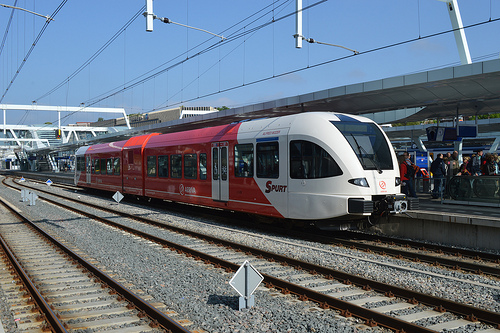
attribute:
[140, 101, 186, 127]
cocrete — off-white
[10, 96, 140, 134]
metal — railing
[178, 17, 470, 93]
wires — metal, cable wires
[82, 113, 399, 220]
train — red and white, engine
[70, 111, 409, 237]
train — set 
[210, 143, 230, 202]
doors — white train 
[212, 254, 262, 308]
sign — informational , train 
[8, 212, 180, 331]
tracks — metal, in the middle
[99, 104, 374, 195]
train — white and red 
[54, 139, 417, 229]
train —  tracks, set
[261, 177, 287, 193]
writing — red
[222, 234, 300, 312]
sign — silver 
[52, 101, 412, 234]
short train — red and white,  short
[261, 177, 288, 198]
word — spurt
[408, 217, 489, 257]
wall — gray, concrete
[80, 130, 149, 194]
car —  passenger , white train , red 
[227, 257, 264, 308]
sign — silver, diamond shaped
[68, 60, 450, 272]
train —  set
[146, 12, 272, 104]
sky — clear blue 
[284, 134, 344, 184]
window — side window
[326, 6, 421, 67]
sky — blue 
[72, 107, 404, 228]
train — red, white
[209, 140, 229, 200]
door — white, double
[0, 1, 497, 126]
sky — crystal clear, blue